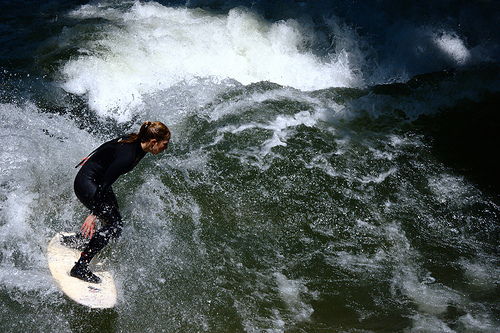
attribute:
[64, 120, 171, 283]
woman — surfing, bent, balanced, surfer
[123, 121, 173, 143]
hair — blonde, wet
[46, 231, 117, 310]
surfboard — white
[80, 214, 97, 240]
hand — bare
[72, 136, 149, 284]
wetsuit — black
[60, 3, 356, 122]
surf — white, agitated, churning, rugged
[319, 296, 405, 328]
water — calm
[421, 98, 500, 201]
shadow — dark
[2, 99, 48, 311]
water — splashing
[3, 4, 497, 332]
water — wild, rugged